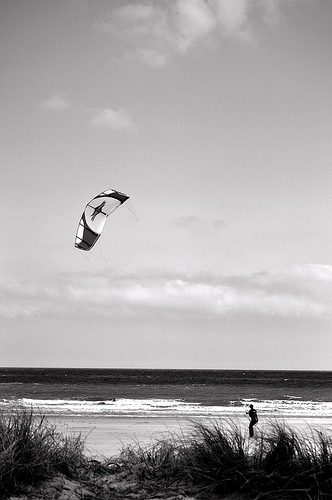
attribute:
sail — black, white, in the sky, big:
[74, 184, 130, 253]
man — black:
[241, 402, 261, 440]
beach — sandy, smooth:
[3, 353, 331, 487]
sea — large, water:
[8, 362, 331, 429]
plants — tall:
[4, 431, 331, 499]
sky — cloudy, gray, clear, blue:
[9, 1, 327, 228]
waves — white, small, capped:
[7, 396, 331, 414]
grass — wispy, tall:
[4, 410, 331, 498]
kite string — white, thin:
[219, 392, 251, 415]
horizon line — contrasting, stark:
[2, 354, 331, 381]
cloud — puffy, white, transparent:
[150, 3, 227, 50]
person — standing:
[247, 403, 259, 434]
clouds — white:
[72, 3, 324, 69]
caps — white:
[37, 396, 190, 409]